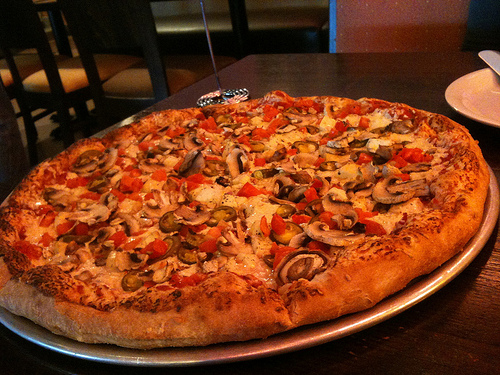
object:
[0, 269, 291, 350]
crust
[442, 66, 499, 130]
plate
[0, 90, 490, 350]
pizza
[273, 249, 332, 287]
mushroom